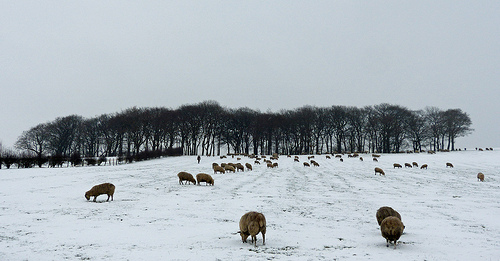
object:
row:
[14, 100, 474, 158]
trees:
[17, 117, 60, 165]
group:
[212, 159, 254, 176]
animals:
[176, 171, 196, 186]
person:
[196, 155, 201, 165]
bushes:
[1, 152, 18, 169]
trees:
[435, 107, 473, 155]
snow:
[7, 151, 499, 259]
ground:
[3, 151, 497, 259]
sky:
[1, 1, 498, 148]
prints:
[267, 170, 353, 207]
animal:
[231, 211, 268, 245]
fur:
[239, 210, 263, 234]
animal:
[83, 182, 117, 202]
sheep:
[195, 173, 214, 185]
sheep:
[178, 171, 196, 184]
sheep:
[374, 167, 387, 176]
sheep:
[476, 172, 485, 180]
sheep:
[379, 216, 406, 247]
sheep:
[377, 206, 402, 224]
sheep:
[303, 162, 310, 167]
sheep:
[446, 162, 454, 167]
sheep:
[420, 164, 428, 170]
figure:
[196, 155, 201, 164]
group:
[249, 151, 320, 168]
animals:
[312, 160, 321, 169]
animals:
[403, 149, 414, 154]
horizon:
[3, 148, 498, 160]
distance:
[3, 125, 496, 162]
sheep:
[373, 158, 379, 162]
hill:
[23, 137, 499, 199]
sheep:
[326, 156, 332, 159]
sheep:
[393, 163, 403, 169]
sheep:
[403, 163, 411, 169]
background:
[2, 95, 499, 185]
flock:
[68, 142, 497, 244]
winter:
[1, 3, 498, 257]